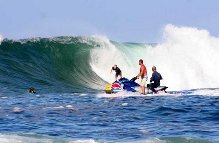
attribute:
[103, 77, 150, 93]
jet ski — brightly colored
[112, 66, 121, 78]
wet suit — black 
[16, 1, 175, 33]
sky — clear, blue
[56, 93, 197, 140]
water — choppy, blue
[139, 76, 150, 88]
trunks — swimming, yellow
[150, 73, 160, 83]
shirt — blue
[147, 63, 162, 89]
person — one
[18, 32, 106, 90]
wave — huge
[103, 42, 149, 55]
color — green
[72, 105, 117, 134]
waters — rough, blue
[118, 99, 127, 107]
wave — white, small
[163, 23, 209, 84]
waves — white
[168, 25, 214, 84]
section — large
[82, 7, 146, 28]
skies — clear, blue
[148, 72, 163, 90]
suit — blue, shiny, wet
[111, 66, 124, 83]
man — one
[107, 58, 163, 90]
people — some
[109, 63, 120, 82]
surfer — one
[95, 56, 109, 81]
wave — one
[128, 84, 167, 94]
ski — jet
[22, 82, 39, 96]
person — one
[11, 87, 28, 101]
water — some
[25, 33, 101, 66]
wave — large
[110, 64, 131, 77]
shirt — black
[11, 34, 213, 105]
wave — large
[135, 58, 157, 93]
man — standing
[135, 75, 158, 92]
shorts — white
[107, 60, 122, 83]
man — surfing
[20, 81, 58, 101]
object — black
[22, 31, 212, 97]
wave — large, crashing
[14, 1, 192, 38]
skies — clear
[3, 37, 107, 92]
wave — cresting